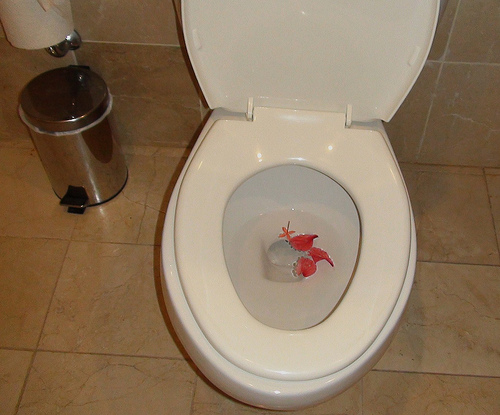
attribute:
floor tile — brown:
[28, 240, 180, 360]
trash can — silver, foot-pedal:
[14, 60, 140, 225]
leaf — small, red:
[294, 253, 320, 287]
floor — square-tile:
[4, 217, 151, 414]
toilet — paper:
[120, 0, 463, 412]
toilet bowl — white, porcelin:
[155, 110, 426, 410]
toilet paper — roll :
[1, 2, 80, 50]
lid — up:
[162, 15, 472, 67]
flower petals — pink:
[278, 218, 338, 277]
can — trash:
[20, 59, 137, 214]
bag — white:
[10, 98, 133, 143]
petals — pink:
[283, 230, 328, 284]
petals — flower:
[276, 225, 336, 283]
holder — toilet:
[21, 20, 100, 56]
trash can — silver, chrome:
[15, 66, 143, 209]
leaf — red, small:
[281, 226, 296, 240]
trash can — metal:
[13, 60, 129, 211]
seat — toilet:
[172, 101, 417, 381]